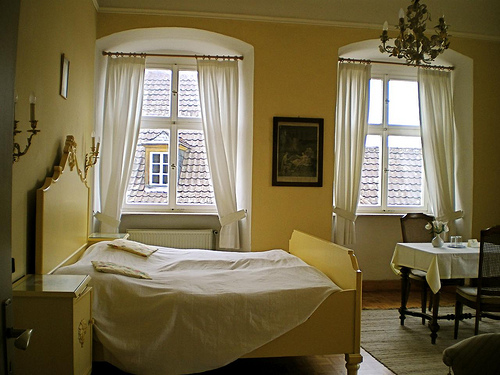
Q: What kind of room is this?
A: Bedroom.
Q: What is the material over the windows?
A: Curtains.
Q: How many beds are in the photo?
A: One.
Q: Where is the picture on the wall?
A: In between the two windows.